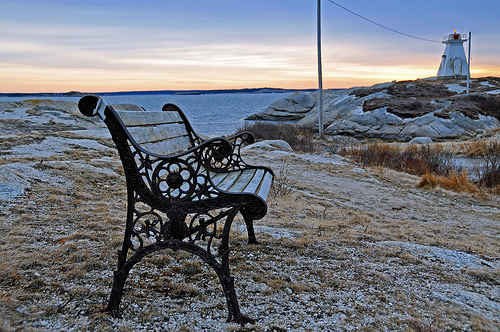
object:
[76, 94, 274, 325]
bench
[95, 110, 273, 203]
ice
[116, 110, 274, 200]
wood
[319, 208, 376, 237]
grass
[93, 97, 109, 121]
snow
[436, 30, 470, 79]
building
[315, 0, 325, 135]
electrical pole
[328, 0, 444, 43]
wire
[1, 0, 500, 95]
sky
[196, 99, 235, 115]
water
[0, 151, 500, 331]
ground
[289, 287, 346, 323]
gravel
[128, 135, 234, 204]
arm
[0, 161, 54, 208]
rocks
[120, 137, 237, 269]
design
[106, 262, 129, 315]
leg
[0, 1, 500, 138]
backgrounud